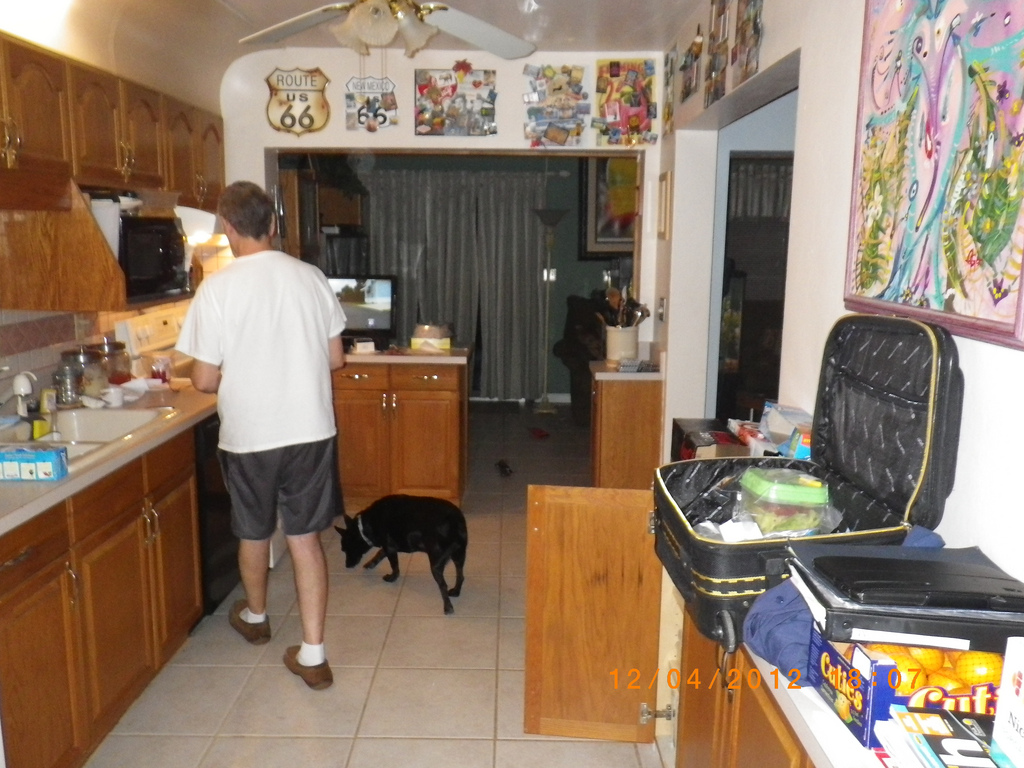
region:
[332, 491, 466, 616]
A black dog in the kitchen.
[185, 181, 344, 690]
A man with gray shorts on.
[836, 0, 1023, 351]
A picture on the wall.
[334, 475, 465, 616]
A dog waiting to be fed.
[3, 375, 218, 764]
Kitchen cupboards and sink in the kitchen.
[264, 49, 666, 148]
Pictures on a wall in the kitchen.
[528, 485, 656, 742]
An open cupboard door.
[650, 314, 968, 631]
A suitcase with food containers in it.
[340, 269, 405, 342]
The television set is on.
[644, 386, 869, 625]
Open black suitcase on counter.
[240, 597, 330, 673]
Person wearing white socks.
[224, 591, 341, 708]
Person wearing brown slip on shoes.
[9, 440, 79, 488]
Blue box on counter top.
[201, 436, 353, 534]
Person wearing gray shorts.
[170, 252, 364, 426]
Person wearing white t-shirt.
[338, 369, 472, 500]
Brown wood kitchen cupboards.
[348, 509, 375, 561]
Gray collar on dog's neck.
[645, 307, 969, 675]
black and gold suitcase sitting on a counter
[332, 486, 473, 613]
black dog sniffing the floor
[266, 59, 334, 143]
metal route 66 decorative sign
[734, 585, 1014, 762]
counter top cluttered with a bunch of stuff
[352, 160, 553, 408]
curtains drawn over a set of sliding doors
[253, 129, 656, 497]
entry way into adjacent room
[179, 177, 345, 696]
man wearing shoes in the house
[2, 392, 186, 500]
white two basin sink in a kitchen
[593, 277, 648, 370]
ceramic crock full of kitchen utensils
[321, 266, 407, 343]
tv sitting on a kitchen counter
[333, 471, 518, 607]
small black dog in kitchen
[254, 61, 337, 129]
route 66 sign on wall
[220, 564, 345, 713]
brown shoes on man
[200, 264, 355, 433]
white t shirt on man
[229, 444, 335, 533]
gray shorts on man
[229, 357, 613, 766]
white tile flooring in kitchen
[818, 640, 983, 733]
box of oranges on counter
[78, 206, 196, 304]
black microwave in kitchen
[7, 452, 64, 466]
blue and white box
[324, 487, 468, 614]
A black dog with a collar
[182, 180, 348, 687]
A man in a white shirt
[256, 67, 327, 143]
A sign on a wall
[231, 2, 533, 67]
A white ceiling fan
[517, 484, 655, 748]
A brown open cupboard door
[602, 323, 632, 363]
A white jar on a counter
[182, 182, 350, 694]
man standing in brown shoes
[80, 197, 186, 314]
large black plastic microwave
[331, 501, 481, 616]
small furry black dog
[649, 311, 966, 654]
large black cloth case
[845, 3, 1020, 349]
large square pink picture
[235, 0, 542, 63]
large wooden white fan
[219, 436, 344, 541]
black cloth shorts on man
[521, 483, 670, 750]
large wooden brown door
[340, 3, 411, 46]
glass white lamp shade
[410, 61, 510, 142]
square painting hung on wall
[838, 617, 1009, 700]
oranges in a box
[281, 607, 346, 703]
man is wearing shoes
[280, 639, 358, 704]
shoes are brown in color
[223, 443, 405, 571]
man is wearing shorts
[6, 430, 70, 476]
small blue box on counter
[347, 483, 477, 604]
dog is black in color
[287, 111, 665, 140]
signs are on the wall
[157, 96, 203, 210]
A door for a cabinet.